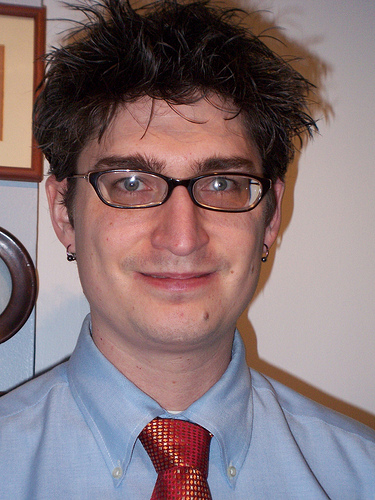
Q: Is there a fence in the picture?
A: No, there are no fences.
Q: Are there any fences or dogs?
A: No, there are no fences or dogs.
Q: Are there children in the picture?
A: No, there are no children.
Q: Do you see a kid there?
A: No, there are no children.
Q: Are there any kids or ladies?
A: No, there are no kids or ladies.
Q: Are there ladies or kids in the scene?
A: No, there are no kids or ladies.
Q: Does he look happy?
A: Yes, the man is happy.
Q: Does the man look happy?
A: Yes, the man is happy.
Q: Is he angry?
A: No, the man is happy.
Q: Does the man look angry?
A: No, the man is happy.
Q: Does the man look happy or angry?
A: The man is happy.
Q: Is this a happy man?
A: Yes, this is a happy man.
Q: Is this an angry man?
A: No, this is a happy man.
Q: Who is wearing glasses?
A: The man is wearing glasses.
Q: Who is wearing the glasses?
A: The man is wearing glasses.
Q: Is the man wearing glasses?
A: Yes, the man is wearing glasses.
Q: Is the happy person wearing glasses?
A: Yes, the man is wearing glasses.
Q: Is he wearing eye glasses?
A: No, the man is wearing glasses.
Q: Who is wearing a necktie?
A: The man is wearing a necktie.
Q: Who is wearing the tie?
A: The man is wearing a necktie.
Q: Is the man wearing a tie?
A: Yes, the man is wearing a tie.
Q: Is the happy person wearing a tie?
A: Yes, the man is wearing a tie.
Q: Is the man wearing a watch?
A: No, the man is wearing a tie.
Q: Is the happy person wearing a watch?
A: No, the man is wearing a tie.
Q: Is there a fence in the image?
A: No, there are no fences.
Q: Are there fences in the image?
A: No, there are no fences.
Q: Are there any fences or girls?
A: No, there are no fences or girls.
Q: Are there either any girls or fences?
A: No, there are no fences or girls.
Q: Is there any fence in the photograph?
A: No, there are no fences.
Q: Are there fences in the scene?
A: No, there are no fences.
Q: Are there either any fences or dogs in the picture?
A: No, there are no fences or dogs.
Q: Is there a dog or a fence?
A: No, there are no fences or dogs.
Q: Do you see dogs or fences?
A: No, there are no fences or dogs.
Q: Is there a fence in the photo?
A: No, there are no fences.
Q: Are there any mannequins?
A: No, there are no mannequins.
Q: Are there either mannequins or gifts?
A: No, there are no mannequins or gifts.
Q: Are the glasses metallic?
A: Yes, the glasses are metallic.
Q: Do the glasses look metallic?
A: Yes, the glasses are metallic.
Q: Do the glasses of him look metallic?
A: Yes, the glasses are metallic.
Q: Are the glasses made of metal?
A: Yes, the glasses are made of metal.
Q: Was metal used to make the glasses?
A: Yes, the glasses are made of metal.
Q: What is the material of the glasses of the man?
A: The glasses are made of metal.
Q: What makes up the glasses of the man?
A: The glasses are made of metal.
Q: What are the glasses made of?
A: The glasses are made of metal.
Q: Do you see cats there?
A: No, there are no cats.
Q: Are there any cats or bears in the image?
A: No, there are no cats or bears.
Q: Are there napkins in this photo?
A: No, there are no napkins.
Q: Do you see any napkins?
A: No, there are no napkins.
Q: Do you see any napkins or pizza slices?
A: No, there are no napkins or pizza slices.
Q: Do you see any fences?
A: No, there are no fences.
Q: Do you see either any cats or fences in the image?
A: No, there are no fences or cats.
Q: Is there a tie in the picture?
A: Yes, there is a tie.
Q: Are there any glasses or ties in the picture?
A: Yes, there is a tie.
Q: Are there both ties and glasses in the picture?
A: Yes, there are both a tie and glasses.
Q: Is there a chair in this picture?
A: No, there are no chairs.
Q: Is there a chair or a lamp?
A: No, there are no chairs or lamps.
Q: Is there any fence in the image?
A: No, there are no fences.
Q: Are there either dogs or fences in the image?
A: No, there are no fences or dogs.